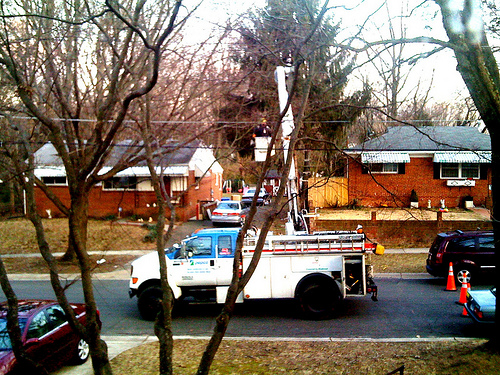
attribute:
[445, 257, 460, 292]
cone — traffic 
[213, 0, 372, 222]
tree — part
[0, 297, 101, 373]
car — red 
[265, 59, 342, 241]
crane — white 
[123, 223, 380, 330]
truck — white 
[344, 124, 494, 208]
house — red 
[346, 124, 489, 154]
roof — black 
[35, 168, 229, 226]
walls — red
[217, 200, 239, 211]
rear window — rear 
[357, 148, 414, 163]
awning — white and green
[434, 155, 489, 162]
awning — white and green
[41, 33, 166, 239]
tree — leafless 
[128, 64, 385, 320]
truck — white and blue, work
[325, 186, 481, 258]
fence — brick , red 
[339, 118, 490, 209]
house — red 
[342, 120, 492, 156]
roof — black 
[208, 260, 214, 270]
door handle — door 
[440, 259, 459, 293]
cone — orange 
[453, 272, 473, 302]
cone — orange 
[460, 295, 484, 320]
cone — orange 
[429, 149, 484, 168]
awning — one 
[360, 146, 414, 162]
awning — one 